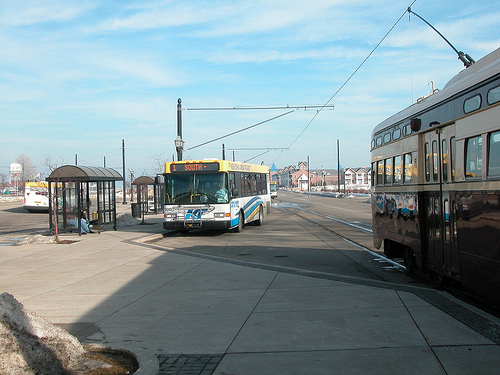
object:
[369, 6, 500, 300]
rail car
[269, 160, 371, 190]
housing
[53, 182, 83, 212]
clear cover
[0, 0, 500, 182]
clouds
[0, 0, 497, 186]
sky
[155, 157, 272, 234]
bus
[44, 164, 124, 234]
bus stop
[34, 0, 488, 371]
scene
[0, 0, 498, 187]
blue sky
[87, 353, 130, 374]
grass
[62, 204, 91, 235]
person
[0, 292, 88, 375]
snow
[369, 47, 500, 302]
bus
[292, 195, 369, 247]
road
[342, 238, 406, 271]
snow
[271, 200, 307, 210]
snow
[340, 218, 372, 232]
snow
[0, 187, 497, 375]
street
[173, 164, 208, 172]
word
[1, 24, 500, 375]
city